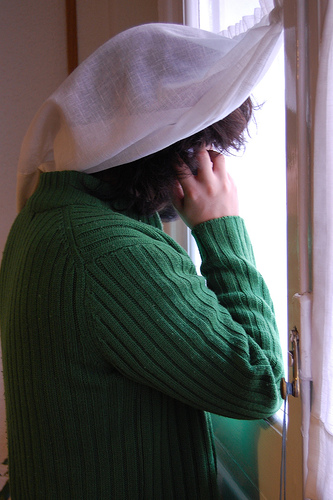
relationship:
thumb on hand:
[166, 180, 187, 212] [167, 148, 236, 226]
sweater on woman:
[0, 214, 280, 454] [9, 23, 280, 452]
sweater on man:
[0, 214, 280, 454] [0, 23, 281, 453]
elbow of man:
[214, 323, 280, 417] [0, 23, 281, 453]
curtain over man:
[19, 25, 274, 171] [0, 23, 281, 453]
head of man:
[68, 24, 252, 207] [0, 23, 281, 453]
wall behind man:
[2, 1, 67, 81] [0, 23, 281, 453]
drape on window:
[19, 25, 274, 171] [269, 38, 283, 320]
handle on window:
[278, 330, 300, 406] [269, 38, 283, 320]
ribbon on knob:
[280, 401, 285, 499] [277, 379, 290, 400]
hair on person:
[96, 155, 189, 213] [3, 24, 280, 452]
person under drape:
[3, 24, 280, 452] [19, 25, 274, 171]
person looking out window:
[3, 24, 280, 452] [269, 38, 283, 320]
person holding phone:
[3, 24, 280, 452] [184, 143, 196, 173]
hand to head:
[167, 148, 236, 226] [68, 24, 252, 207]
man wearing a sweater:
[0, 23, 281, 453] [0, 214, 280, 454]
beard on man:
[158, 202, 176, 227] [0, 23, 281, 453]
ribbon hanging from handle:
[280, 401, 285, 499] [278, 330, 300, 406]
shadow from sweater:
[216, 417, 254, 480] [0, 214, 280, 454]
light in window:
[262, 45, 284, 272] [269, 38, 283, 320]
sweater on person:
[0, 214, 280, 454] [3, 24, 280, 452]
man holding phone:
[0, 23, 281, 453] [184, 143, 196, 173]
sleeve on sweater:
[197, 220, 281, 418] [0, 214, 280, 454]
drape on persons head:
[19, 25, 274, 171] [68, 24, 252, 207]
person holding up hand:
[3, 24, 280, 452] [167, 148, 236, 226]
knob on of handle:
[277, 379, 290, 400] [278, 330, 300, 406]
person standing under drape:
[3, 24, 280, 452] [19, 25, 274, 171]